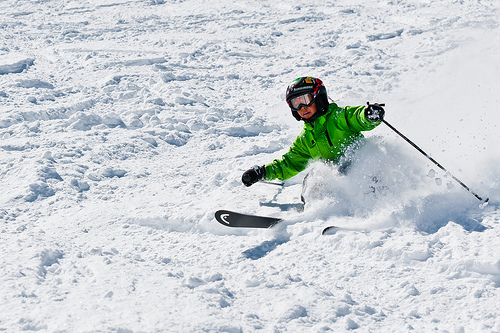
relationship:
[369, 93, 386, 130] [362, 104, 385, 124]
glove in hand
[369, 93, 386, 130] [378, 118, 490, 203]
glove holding poles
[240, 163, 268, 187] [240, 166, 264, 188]
glove on hand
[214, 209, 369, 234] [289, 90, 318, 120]
skis has face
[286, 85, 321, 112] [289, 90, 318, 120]
glasses on face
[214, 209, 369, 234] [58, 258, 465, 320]
skis on snow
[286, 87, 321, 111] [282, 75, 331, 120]
glasses on head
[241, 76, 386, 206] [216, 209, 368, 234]
him standing on skis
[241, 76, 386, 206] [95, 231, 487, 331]
him falling on snow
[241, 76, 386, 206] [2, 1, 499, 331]
him skiing down hill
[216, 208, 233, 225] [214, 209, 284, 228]
symbol on ski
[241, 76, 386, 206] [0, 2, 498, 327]
him buried in snow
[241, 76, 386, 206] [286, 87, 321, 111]
him wearing glasses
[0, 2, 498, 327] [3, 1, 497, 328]
snow covering ground